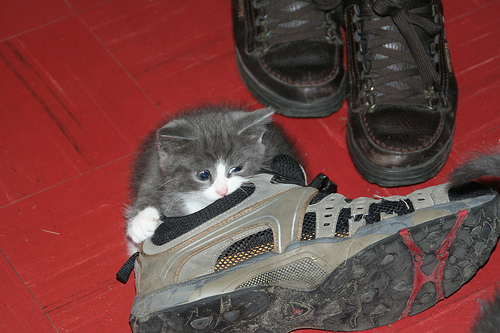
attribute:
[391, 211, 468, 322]
x — red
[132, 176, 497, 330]
shoe — dirty, grey, black, red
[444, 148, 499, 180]
tail — gray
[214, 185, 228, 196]
nose — pink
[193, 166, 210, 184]
kitten — tiny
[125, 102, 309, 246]
kitten — gray, white, small, feline, pet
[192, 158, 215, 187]
eye — blue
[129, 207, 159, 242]
paw — white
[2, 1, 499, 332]
tile — red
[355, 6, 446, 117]
lace — brown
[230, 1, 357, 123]
show — brown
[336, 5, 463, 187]
shoe — brown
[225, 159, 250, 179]
eye — blue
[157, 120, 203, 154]
ear — gray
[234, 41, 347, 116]
sole — black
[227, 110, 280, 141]
ear — grey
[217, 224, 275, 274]
mesh — black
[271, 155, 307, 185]
tongue — black